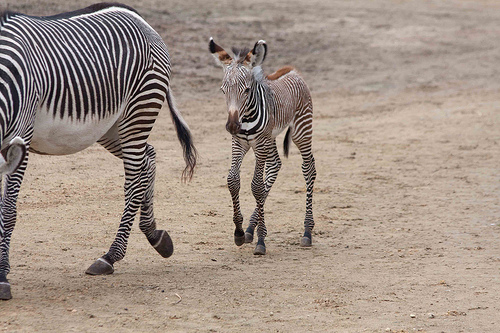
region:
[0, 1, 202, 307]
the zebra in the front is big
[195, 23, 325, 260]
the zebra in the back is small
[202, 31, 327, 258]
the zebra is young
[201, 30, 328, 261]
the zebra is a baby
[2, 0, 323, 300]
the zebras are striped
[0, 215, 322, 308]
the zebras have hooves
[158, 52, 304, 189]
the zebras have tails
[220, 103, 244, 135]
the zebra has a black nose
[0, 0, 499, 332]
the ground is dirt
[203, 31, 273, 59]
the zebras ears have white tips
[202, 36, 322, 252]
Young one of a donkey walking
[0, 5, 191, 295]
Adult zebra walking in the wild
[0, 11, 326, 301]
Two zebras walking in wild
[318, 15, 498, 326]
Very dry bare ground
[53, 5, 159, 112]
Black and white stripes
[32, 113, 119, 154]
White under belly of zebra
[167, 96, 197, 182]
Short black tail of zebra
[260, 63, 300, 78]
Brown part of zebra's back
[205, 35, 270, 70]
Ears of young zebra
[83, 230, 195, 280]
Black hard zebra's hooves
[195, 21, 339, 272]
baby zebra with mom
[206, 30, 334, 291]
baby zebra with knobby knees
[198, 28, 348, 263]
baby zebra behind mom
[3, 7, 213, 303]
mother zebra in front of child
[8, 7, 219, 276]
larger zebra walking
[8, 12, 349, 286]
two zebras in wild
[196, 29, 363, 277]
baby zebra with brownish fur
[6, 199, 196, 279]
zebra with one hoof up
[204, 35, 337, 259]
baby zebra with shorter tail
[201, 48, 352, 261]
baby zebra with many stripes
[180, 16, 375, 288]
A small zebra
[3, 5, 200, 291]
a large zebra's body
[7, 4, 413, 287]
two zebras running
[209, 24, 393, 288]
a zebra walking on the ground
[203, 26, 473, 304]
a zebra in a sandy area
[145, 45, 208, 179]
an adult zebra's tail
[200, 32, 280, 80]
a young zebra's ears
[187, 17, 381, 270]
a young zebra standing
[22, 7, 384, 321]
a young zebra following the adult zebra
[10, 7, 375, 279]
an adult zebra leading a young zebra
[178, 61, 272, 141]
face of baby zebra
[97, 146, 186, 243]
striped legs of adult zebra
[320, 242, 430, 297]
gravel that zebras are on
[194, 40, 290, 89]
ears of baby zebra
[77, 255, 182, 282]
left hoove of zebra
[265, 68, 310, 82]
back fur of baby zebra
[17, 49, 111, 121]
striped print of adult zebra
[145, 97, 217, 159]
tail of adult zebra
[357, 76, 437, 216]
gravel that zebras run along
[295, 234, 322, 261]
back left hoove of zebra